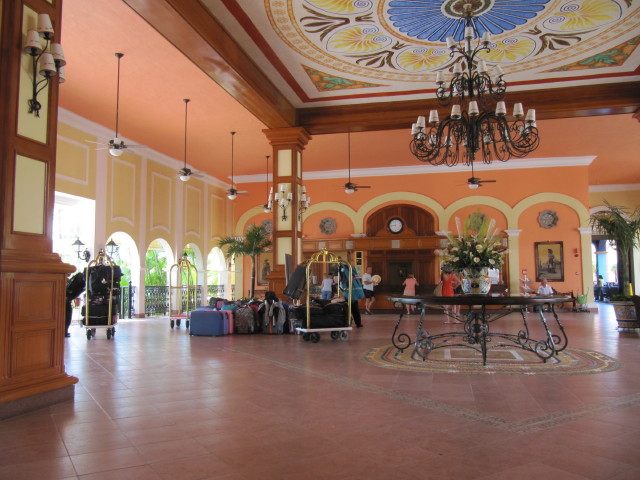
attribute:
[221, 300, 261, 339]
suitcase — tan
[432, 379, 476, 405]
tile — red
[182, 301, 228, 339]
suitcase — blue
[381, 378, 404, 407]
tile — red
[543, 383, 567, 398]
tile — red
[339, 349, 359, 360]
tile — red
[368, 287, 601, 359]
table — metal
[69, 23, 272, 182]
ceiling — pink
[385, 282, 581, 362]
table — BLACK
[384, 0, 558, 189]
chandelier — hanging